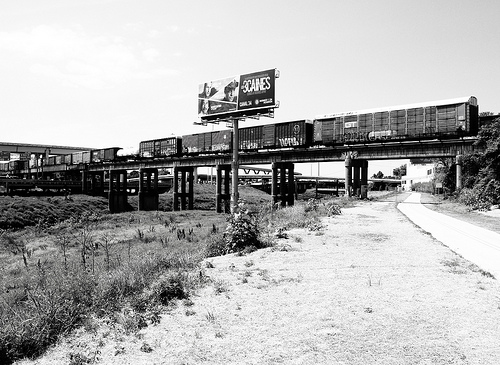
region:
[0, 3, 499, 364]
Photograph is in black and white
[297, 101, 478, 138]
A large, train car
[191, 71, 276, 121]
Billboard high in the air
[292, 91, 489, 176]
Train on a bridge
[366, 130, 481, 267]
A roadway under a bridge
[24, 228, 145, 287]
Large area of grass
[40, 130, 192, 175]
Several train cars in a row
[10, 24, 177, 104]
Clouds in the sky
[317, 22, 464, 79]
Large body of the sky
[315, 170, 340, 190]
Bridge in the distance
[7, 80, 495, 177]
this is a freight train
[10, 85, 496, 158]
the train is on tracks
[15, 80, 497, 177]
the tracks are an overpass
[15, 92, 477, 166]
the train is on an overpass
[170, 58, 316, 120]
this is a billboard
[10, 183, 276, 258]
this is a dry creaked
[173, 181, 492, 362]
this is dirt and weeds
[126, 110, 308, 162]
there is graffiti on the sides of the cars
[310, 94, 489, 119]
the roof of this car is white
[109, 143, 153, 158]
this is an oil tank car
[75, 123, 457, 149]
train on the tracks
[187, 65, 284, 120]
billboard on the pole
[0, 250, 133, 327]
weeds on the ground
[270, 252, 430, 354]
sand on the ground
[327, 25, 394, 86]
sky is mostly clear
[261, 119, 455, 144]
cars of the train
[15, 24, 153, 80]
few clouds in sky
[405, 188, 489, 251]
road on the side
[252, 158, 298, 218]
bottom of the tracks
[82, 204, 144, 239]
sand on the ground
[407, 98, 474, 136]
cargo of a train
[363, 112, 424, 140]
cargo of a train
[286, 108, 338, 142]
cargo of a train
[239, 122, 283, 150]
cargo of a train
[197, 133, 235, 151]
cargo of a train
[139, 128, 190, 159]
cargo of a train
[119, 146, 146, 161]
cargo of a train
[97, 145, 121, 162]
cargo of a train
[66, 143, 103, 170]
cargo of a train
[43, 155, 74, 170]
cargo of a train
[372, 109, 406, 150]
cargo of a train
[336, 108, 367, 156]
cargo of a train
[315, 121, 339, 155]
cargo of a train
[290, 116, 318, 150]
cargo of a train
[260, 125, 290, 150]
cargo of a train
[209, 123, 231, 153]
cargo of a train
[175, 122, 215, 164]
cargo of a train